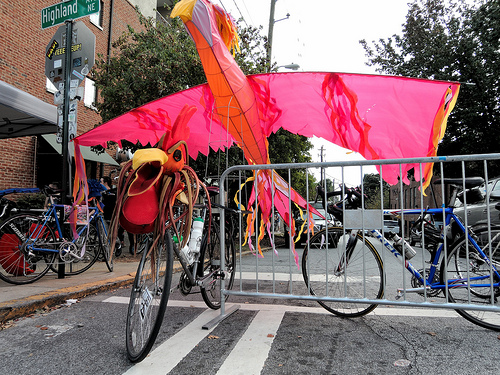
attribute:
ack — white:
[203, 147, 496, 350]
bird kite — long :
[71, 5, 461, 259]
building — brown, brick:
[13, 14, 198, 242]